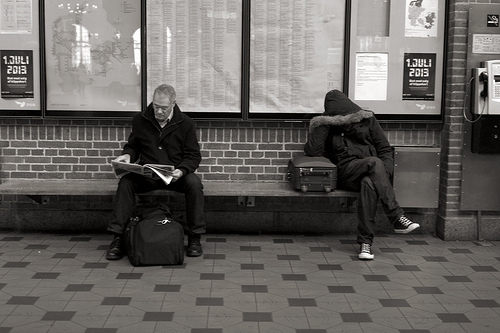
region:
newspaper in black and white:
[110, 160, 172, 178]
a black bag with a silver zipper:
[132, 218, 184, 265]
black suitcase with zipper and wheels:
[290, 155, 335, 192]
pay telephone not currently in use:
[474, 62, 499, 118]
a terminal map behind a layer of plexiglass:
[45, 0, 142, 109]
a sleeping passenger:
[325, 90, 413, 259]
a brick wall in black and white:
[205, 135, 278, 177]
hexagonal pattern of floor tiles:
[149, 268, 381, 331]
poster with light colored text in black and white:
[2, 50, 33, 97]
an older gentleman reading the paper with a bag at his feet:
[115, 84, 200, 261]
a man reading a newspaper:
[91, 75, 222, 222]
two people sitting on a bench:
[71, 87, 408, 229]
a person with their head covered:
[285, 79, 382, 196]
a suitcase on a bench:
[278, 140, 336, 209]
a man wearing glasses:
[148, 85, 191, 130]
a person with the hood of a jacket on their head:
[297, 94, 404, 170]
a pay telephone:
[468, 52, 495, 131]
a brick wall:
[1, 124, 118, 189]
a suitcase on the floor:
[112, 202, 192, 280]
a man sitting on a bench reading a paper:
[33, 82, 249, 276]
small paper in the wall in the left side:
[0, 45, 32, 100]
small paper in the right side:
[405, 53, 435, 108]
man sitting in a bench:
[105, 85, 207, 262]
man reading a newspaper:
[108, 153, 179, 184]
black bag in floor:
[127, 195, 181, 266]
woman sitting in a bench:
[308, 89, 420, 260]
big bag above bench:
[288, 151, 338, 192]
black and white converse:
[358, 215, 420, 267]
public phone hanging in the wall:
[472, 58, 497, 118]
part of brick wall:
[0, 126, 441, 180]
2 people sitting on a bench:
[91, 52, 430, 267]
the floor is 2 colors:
[100, 254, 412, 331]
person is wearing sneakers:
[340, 202, 433, 285]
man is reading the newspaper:
[90, 70, 224, 223]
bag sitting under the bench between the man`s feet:
[101, 189, 208, 274]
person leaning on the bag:
[263, 79, 358, 211]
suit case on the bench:
[267, 135, 339, 203]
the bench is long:
[0, 150, 392, 216]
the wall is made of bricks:
[39, 129, 279, 179]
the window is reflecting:
[27, 5, 229, 126]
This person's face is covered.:
[306, 65, 416, 245]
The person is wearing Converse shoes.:
[338, 208, 435, 263]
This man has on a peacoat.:
[97, 73, 240, 268]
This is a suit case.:
[278, 151, 340, 211]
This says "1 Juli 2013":
[397, 43, 443, 109]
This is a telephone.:
[457, 50, 494, 132]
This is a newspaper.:
[110, 133, 202, 208]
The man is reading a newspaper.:
[101, 80, 219, 241]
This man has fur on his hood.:
[285, 71, 410, 169]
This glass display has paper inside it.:
[56, 4, 333, 115]